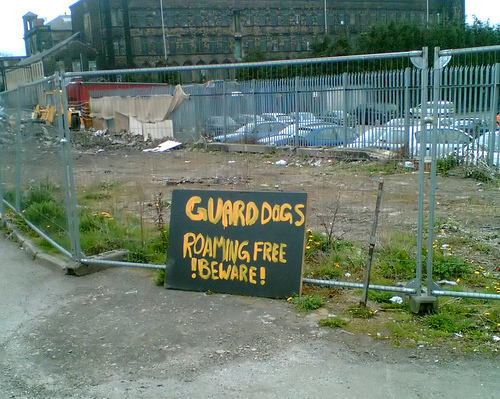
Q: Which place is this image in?
A: It is at the field.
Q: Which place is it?
A: It is a field.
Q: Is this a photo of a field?
A: Yes, it is showing a field.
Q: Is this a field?
A: Yes, it is a field.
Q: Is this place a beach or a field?
A: It is a field.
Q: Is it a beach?
A: No, it is a field.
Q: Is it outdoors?
A: Yes, it is outdoors.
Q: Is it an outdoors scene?
A: Yes, it is outdoors.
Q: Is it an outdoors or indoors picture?
A: It is outdoors.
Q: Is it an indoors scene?
A: No, it is outdoors.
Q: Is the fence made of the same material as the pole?
A: Yes, both the fence and the pole are made of metal.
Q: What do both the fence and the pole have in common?
A: The material, both the fence and the pole are metallic.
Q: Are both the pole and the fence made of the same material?
A: Yes, both the pole and the fence are made of metal.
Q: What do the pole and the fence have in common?
A: The material, both the pole and the fence are metallic.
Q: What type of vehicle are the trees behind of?
A: The trees are behind the cars.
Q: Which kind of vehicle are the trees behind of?
A: The trees are behind the cars.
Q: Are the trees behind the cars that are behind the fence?
A: Yes, the trees are behind the cars.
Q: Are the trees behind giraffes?
A: No, the trees are behind the cars.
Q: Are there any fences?
A: Yes, there is a fence.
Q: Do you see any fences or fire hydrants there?
A: Yes, there is a fence.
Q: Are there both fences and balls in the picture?
A: No, there is a fence but no balls.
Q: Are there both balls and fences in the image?
A: No, there is a fence but no balls.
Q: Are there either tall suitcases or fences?
A: Yes, there is a tall fence.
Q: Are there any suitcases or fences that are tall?
A: Yes, the fence is tall.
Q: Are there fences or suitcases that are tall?
A: Yes, the fence is tall.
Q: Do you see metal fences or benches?
A: Yes, there is a metal fence.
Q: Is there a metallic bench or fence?
A: Yes, there is a metal fence.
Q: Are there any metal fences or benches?
A: Yes, there is a metal fence.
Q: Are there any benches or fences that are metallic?
A: Yes, the fence is metallic.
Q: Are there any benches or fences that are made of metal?
A: Yes, the fence is made of metal.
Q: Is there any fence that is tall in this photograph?
A: Yes, there is a tall fence.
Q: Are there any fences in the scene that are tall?
A: Yes, there is a fence that is tall.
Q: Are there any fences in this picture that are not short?
A: Yes, there is a tall fence.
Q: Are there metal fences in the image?
A: Yes, there is a metal fence.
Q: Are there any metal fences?
A: Yes, there is a metal fence.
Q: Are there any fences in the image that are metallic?
A: Yes, there is a fence that is metallic.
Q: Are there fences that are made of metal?
A: Yes, there is a fence that is made of metal.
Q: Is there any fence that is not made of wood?
A: Yes, there is a fence that is made of metal.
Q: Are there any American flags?
A: No, there are no American flags.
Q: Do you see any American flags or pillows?
A: No, there are no American flags or pillows.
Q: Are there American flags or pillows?
A: No, there are no American flags or pillows.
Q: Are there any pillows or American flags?
A: No, there are no American flags or pillows.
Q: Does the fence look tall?
A: Yes, the fence is tall.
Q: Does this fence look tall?
A: Yes, the fence is tall.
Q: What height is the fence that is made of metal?
A: The fence is tall.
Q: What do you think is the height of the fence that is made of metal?
A: The fence is tall.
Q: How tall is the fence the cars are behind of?
A: The fence is tall.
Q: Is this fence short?
A: No, the fence is tall.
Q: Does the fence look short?
A: No, the fence is tall.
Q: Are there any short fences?
A: No, there is a fence but it is tall.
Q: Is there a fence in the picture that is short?
A: No, there is a fence but it is tall.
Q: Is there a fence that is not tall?
A: No, there is a fence but it is tall.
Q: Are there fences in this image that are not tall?
A: No, there is a fence but it is tall.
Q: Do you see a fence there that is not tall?
A: No, there is a fence but it is tall.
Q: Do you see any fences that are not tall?
A: No, there is a fence but it is tall.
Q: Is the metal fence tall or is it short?
A: The fence is tall.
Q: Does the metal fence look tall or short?
A: The fence is tall.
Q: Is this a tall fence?
A: Yes, this is a tall fence.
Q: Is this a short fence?
A: No, this is a tall fence.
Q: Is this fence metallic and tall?
A: Yes, the fence is metallic and tall.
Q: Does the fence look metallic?
A: Yes, the fence is metallic.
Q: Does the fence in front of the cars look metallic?
A: Yes, the fence is metallic.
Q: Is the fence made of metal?
A: Yes, the fence is made of metal.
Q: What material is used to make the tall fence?
A: The fence is made of metal.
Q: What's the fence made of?
A: The fence is made of metal.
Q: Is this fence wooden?
A: No, the fence is metallic.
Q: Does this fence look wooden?
A: No, the fence is metallic.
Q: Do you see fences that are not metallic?
A: No, there is a fence but it is metallic.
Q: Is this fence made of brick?
A: No, the fence is made of metal.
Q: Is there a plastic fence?
A: No, there is a fence but it is made of metal.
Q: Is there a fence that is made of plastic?
A: No, there is a fence but it is made of metal.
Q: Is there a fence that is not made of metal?
A: No, there is a fence but it is made of metal.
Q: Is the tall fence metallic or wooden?
A: The fence is metallic.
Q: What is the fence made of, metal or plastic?
A: The fence is made of metal.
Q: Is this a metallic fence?
A: Yes, this is a metallic fence.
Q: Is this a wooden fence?
A: No, this is a metallic fence.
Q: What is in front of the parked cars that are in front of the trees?
A: The fence is in front of the cars.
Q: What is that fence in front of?
A: The fence is in front of the cars.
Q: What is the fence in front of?
A: The fence is in front of the cars.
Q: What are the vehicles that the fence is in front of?
A: The vehicles are cars.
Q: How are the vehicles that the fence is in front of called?
A: The vehicles are cars.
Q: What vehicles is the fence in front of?
A: The fence is in front of the cars.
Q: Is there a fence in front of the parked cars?
A: Yes, there is a fence in front of the cars.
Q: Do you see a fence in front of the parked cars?
A: Yes, there is a fence in front of the cars.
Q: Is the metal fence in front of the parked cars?
A: Yes, the fence is in front of the cars.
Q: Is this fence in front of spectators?
A: No, the fence is in front of the cars.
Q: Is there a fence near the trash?
A: Yes, there is a fence near the trash.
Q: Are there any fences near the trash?
A: Yes, there is a fence near the trash.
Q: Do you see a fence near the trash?
A: Yes, there is a fence near the trash.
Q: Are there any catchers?
A: No, there are no catchers.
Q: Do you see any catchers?
A: No, there are no catchers.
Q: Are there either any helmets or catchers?
A: No, there are no catchers or helmets.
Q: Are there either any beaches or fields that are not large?
A: No, there is a field but it is large.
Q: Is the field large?
A: Yes, the field is large.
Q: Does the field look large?
A: Yes, the field is large.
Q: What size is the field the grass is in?
A: The field is large.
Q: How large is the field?
A: The field is large.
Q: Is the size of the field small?
A: No, the field is large.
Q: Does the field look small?
A: No, the field is large.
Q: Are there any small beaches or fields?
A: No, there is a field but it is large.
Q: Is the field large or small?
A: The field is large.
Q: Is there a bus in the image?
A: No, there are no buses.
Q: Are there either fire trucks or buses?
A: No, there are no buses or fire trucks.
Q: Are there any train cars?
A: No, there are no train cars.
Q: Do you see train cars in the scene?
A: No, there are no train cars.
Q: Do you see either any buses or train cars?
A: No, there are no train cars or buses.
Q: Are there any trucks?
A: No, there are no trucks.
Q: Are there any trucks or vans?
A: No, there are no trucks or vans.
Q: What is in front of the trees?
A: The cars are in front of the trees.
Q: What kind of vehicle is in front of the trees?
A: The vehicles are cars.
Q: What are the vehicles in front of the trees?
A: The vehicles are cars.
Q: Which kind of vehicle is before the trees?
A: The vehicles are cars.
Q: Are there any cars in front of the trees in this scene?
A: Yes, there are cars in front of the trees.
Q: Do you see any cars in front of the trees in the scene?
A: Yes, there are cars in front of the trees.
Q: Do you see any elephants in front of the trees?
A: No, there are cars in front of the trees.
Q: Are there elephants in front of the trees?
A: No, there are cars in front of the trees.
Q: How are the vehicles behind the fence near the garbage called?
A: The vehicles are cars.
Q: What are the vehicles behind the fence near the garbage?
A: The vehicles are cars.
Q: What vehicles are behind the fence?
A: The vehicles are cars.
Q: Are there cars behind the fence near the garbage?
A: Yes, there are cars behind the fence.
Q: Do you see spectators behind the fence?
A: No, there are cars behind the fence.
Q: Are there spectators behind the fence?
A: No, there are cars behind the fence.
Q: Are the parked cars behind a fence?
A: Yes, the cars are behind a fence.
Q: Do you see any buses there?
A: No, there are no buses.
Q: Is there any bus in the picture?
A: No, there are no buses.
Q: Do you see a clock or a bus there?
A: No, there are no buses or clocks.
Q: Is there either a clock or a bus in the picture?
A: No, there are no buses or clocks.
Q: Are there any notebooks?
A: No, there are no notebooks.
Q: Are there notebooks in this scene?
A: No, there are no notebooks.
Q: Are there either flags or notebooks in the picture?
A: No, there are no notebooks or flags.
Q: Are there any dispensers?
A: No, there are no dispensers.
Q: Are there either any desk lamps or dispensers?
A: No, there are no dispensers or desk lamps.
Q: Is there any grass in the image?
A: Yes, there is grass.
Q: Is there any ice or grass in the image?
A: Yes, there is grass.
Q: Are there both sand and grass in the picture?
A: No, there is grass but no sand.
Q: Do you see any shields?
A: No, there are no shields.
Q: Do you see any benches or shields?
A: No, there are no shields or benches.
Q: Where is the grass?
A: The grass is in the field.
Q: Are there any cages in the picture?
A: No, there are no cages.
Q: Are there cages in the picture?
A: No, there are no cages.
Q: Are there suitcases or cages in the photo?
A: No, there are no cages or suitcases.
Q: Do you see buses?
A: No, there are no buses.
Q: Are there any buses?
A: No, there are no buses.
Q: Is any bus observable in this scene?
A: No, there are no buses.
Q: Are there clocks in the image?
A: No, there are no clocks.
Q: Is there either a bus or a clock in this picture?
A: No, there are no clocks or buses.